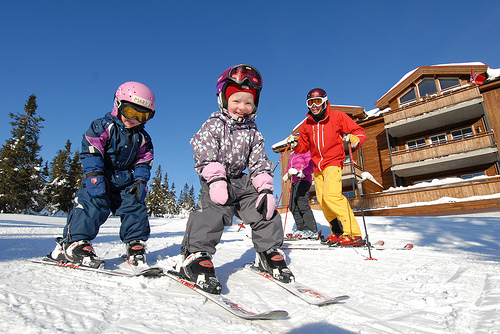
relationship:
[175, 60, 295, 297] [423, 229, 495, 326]
toddler skiing on snow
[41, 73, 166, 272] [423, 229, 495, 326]
toddler skiing on snow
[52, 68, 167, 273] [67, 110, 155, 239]
toddler wearing snowsuit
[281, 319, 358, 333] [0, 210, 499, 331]
shadow in snow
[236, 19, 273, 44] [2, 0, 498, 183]
white clouds in blue sky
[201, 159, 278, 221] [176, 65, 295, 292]
gloves worn by child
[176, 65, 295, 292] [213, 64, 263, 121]
child wearing purple helmet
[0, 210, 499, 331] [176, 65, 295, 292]
snow next to child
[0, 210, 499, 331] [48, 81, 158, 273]
snow next to child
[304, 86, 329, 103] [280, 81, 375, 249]
helmet worn by man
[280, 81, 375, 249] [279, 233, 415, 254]
man on skis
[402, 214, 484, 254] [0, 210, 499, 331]
shadow of object on snow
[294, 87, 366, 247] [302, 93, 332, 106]
person wearing spects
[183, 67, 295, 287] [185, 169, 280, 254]
kid wearing pants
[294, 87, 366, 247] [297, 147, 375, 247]
person wearing pants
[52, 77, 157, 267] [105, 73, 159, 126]
girl wearing helmet